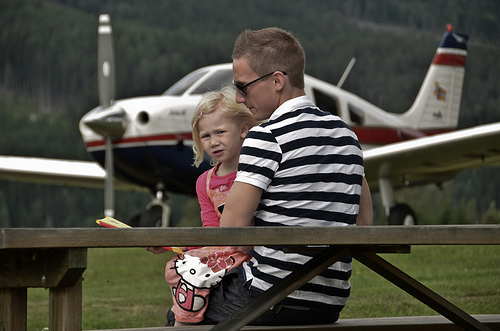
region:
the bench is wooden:
[393, 222, 404, 244]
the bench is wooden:
[389, 220, 403, 262]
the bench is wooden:
[377, 226, 389, 270]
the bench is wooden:
[377, 222, 389, 248]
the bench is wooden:
[371, 221, 386, 255]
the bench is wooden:
[366, 214, 372, 250]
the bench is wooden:
[369, 219, 382, 234]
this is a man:
[235, 25, 337, 247]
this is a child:
[190, 98, 242, 198]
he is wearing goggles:
[234, 75, 256, 95]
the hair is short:
[243, 27, 269, 51]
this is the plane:
[90, 99, 172, 166]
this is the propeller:
[83, 5, 133, 217]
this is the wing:
[429, 116, 497, 180]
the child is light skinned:
[225, 127, 239, 142]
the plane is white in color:
[149, 99, 176, 126]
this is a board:
[330, 224, 356, 245]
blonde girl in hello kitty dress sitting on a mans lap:
[168, 87, 258, 327]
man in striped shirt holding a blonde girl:
[219, 22, 375, 322]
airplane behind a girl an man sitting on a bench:
[2, 5, 499, 251]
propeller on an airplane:
[82, 7, 133, 222]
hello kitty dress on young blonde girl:
[164, 159, 259, 328]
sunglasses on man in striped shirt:
[227, 65, 294, 106]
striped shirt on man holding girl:
[237, 96, 371, 315]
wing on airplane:
[367, 116, 499, 180]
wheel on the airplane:
[384, 200, 419, 235]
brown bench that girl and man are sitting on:
[3, 218, 499, 324]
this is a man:
[225, 33, 369, 243]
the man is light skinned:
[256, 93, 283, 103]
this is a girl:
[195, 110, 242, 180]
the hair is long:
[192, 143, 202, 167]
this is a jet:
[124, 90, 177, 150]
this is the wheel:
[392, 198, 420, 227]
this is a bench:
[79, 217, 484, 317]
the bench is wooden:
[329, 228, 444, 249]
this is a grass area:
[433, 254, 494, 290]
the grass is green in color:
[456, 252, 481, 277]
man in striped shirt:
[203, 17, 419, 327]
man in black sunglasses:
[210, 17, 380, 324]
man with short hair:
[209, 25, 366, 325]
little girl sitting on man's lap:
[151, 72, 252, 329]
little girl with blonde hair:
[155, 80, 262, 330]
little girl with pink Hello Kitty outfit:
[163, 77, 258, 324]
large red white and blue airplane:
[2, 4, 497, 244]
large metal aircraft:
[0, 0, 498, 231]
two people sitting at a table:
[135, 22, 390, 325]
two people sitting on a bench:
[147, 22, 370, 327]